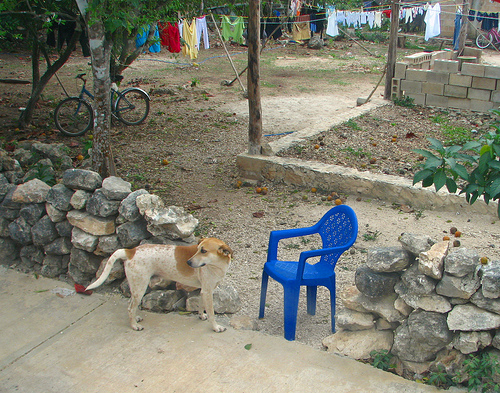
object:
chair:
[258, 201, 360, 341]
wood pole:
[241, 0, 266, 156]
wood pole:
[380, 1, 400, 101]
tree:
[409, 108, 500, 220]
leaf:
[409, 149, 441, 160]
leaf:
[413, 169, 435, 186]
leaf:
[433, 168, 447, 192]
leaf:
[461, 141, 482, 151]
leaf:
[443, 156, 456, 170]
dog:
[87, 236, 234, 335]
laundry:
[325, 11, 388, 30]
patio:
[256, 66, 498, 202]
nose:
[182, 257, 192, 268]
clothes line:
[127, 2, 497, 60]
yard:
[1, 0, 498, 345]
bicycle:
[48, 68, 155, 139]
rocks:
[207, 205, 296, 235]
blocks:
[386, 43, 499, 117]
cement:
[2, 265, 446, 393]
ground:
[4, 37, 498, 272]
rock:
[102, 176, 132, 201]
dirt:
[3, 38, 497, 353]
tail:
[83, 247, 124, 290]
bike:
[475, 25, 499, 47]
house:
[416, 0, 498, 49]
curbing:
[232, 123, 362, 192]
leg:
[279, 283, 303, 347]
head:
[186, 238, 231, 269]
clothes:
[329, 14, 337, 36]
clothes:
[423, 4, 438, 38]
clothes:
[182, 21, 199, 56]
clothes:
[195, 17, 210, 48]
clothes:
[220, 17, 242, 42]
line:
[262, 17, 325, 22]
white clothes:
[325, 10, 384, 37]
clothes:
[141, 17, 243, 52]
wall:
[320, 231, 499, 386]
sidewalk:
[1, 259, 474, 393]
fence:
[323, 231, 500, 393]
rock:
[355, 265, 402, 299]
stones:
[320, 225, 498, 387]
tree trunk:
[16, 33, 80, 132]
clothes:
[133, 17, 161, 64]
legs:
[327, 284, 344, 334]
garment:
[168, 21, 211, 59]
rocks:
[44, 183, 75, 211]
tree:
[66, 1, 220, 123]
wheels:
[52, 95, 96, 137]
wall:
[394, 64, 497, 124]